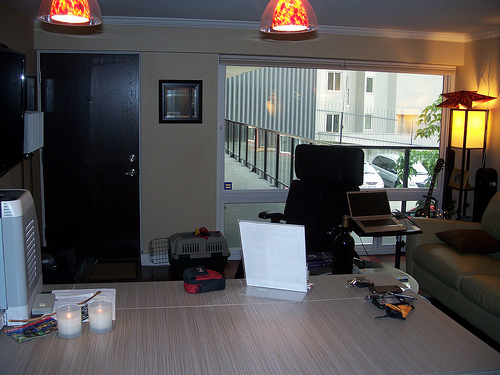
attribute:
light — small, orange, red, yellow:
[33, 0, 104, 35]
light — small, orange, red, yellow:
[257, 0, 320, 42]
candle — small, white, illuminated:
[56, 299, 82, 339]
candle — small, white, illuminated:
[86, 297, 114, 334]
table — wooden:
[1, 269, 499, 374]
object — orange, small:
[366, 294, 416, 322]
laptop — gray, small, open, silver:
[346, 189, 406, 237]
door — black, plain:
[39, 51, 141, 281]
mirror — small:
[157, 78, 202, 126]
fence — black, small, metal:
[225, 116, 438, 210]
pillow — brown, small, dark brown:
[434, 228, 498, 254]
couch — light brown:
[403, 189, 499, 359]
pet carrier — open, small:
[148, 225, 231, 278]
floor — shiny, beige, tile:
[43, 254, 408, 284]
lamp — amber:
[445, 107, 489, 220]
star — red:
[435, 90, 498, 111]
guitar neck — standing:
[418, 157, 444, 217]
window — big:
[223, 66, 449, 252]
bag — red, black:
[181, 263, 225, 294]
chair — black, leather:
[234, 143, 364, 279]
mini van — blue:
[371, 153, 433, 188]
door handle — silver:
[123, 167, 136, 178]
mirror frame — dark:
[157, 76, 204, 125]